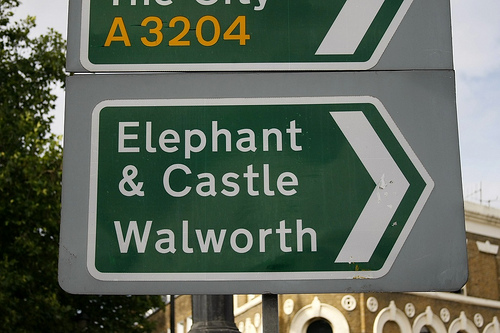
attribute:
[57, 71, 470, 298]
sign — green, for traffic, indicating, metallic, gray, grey, in english, white green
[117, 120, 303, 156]
letters — in english, white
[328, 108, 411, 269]
arrow — pointing, white, green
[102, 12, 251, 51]
letters — yellow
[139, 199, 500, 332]
building — brown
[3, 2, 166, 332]
tree — green, tall, in the background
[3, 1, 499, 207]
sky — cloudy, overcast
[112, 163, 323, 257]
words — in english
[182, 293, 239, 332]
pole — metal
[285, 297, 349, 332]
arch — white